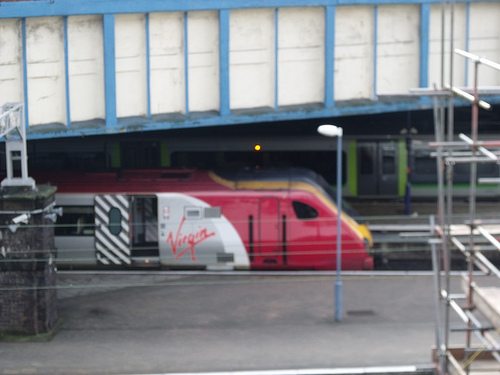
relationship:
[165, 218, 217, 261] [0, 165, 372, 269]
name on car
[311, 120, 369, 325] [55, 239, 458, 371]
pole near platform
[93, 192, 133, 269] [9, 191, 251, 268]
door on car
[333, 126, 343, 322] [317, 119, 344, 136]
pole has light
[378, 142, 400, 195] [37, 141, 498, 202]
door on train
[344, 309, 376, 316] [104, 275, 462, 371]
vent in ground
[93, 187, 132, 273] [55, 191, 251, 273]
door of car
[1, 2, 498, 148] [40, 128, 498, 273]
overpass over trains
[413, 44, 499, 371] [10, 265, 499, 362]
scaffolding by platform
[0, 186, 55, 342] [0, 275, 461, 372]
brick post on ground